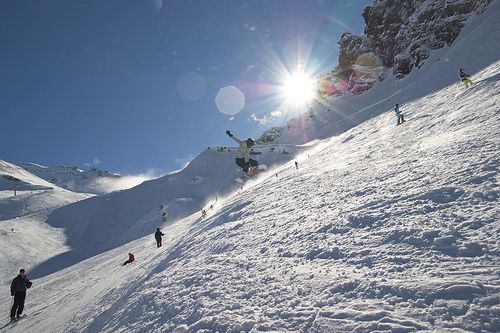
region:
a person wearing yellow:
[453, 64, 474, 91]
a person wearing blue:
[387, 99, 407, 129]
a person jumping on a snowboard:
[218, 127, 273, 187]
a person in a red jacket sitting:
[120, 245, 137, 267]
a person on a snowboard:
[0, 262, 41, 329]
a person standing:
[152, 225, 165, 253]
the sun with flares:
[242, 32, 338, 144]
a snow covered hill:
[1, 156, 76, 231]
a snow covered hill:
[23, 156, 166, 198]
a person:
[291, 153, 307, 174]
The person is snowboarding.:
[215, 117, 277, 209]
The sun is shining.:
[257, 48, 355, 131]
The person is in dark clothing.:
[8, 254, 46, 331]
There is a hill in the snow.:
[177, 136, 236, 206]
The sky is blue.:
[27, 90, 114, 196]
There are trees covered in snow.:
[331, 15, 455, 92]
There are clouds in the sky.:
[89, 149, 171, 209]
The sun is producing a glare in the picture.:
[207, 53, 289, 139]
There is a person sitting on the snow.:
[108, 244, 139, 286]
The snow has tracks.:
[307, 185, 373, 279]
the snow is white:
[235, 172, 337, 323]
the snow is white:
[295, 212, 372, 326]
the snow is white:
[328, 265, 375, 326]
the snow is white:
[334, 218, 382, 318]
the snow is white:
[315, 301, 346, 331]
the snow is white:
[327, 234, 359, 324]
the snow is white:
[300, 262, 341, 320]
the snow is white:
[287, 275, 325, 329]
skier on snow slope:
[388, 99, 413, 131]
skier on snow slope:
[454, 64, 474, 97]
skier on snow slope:
[227, 133, 267, 201]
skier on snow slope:
[148, 228, 168, 254]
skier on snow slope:
[116, 246, 138, 266]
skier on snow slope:
[1, 267, 43, 329]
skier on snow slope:
[158, 210, 170, 217]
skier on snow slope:
[289, 155, 301, 170]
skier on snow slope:
[187, 170, 197, 185]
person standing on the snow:
[7, 266, 52, 325]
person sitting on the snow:
[113, 251, 141, 266]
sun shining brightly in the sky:
[247, 62, 342, 120]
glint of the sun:
[204, 80, 244, 118]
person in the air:
[218, 116, 278, 181]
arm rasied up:
[218, 121, 243, 145]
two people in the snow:
[385, 61, 492, 150]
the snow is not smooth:
[176, 243, 493, 322]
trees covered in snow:
[310, 0, 459, 95]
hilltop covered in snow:
[181, 138, 235, 167]